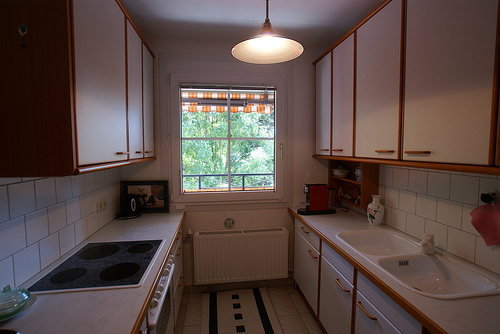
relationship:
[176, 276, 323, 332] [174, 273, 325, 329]
tiles on floor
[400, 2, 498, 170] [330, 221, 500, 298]
cabinet above sink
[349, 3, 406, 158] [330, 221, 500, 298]
cabinet above sink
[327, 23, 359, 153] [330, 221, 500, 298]
cabinet above sink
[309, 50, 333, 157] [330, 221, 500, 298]
cabinet above sink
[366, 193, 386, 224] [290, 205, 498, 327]
dish on countertop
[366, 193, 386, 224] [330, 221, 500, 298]
vase next to sink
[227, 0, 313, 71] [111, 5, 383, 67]
light hanging from ceiling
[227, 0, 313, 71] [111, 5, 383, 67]
light on ceiling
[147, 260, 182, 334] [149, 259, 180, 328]
stove with handle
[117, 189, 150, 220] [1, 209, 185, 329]
kettle on counter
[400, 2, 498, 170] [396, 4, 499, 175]
cabinet with frame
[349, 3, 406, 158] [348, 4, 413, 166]
cabinet with frame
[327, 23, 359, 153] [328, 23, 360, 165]
cabinet with frame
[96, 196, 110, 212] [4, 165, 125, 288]
outlet on wall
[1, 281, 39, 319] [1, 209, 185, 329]
dish on counter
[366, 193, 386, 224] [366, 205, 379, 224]
vase with design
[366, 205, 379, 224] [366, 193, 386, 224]
design on vase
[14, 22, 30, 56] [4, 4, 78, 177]
picture on end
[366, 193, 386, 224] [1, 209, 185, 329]
dish on counter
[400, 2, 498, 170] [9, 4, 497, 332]
cabinet in kitchen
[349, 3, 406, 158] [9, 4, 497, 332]
cabinet in kitchen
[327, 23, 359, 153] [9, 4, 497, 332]
cabinet in kitchen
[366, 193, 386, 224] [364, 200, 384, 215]
vase with flower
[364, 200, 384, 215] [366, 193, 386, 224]
flower on vase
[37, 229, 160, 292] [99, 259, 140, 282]
stovetop with element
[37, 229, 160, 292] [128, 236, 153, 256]
stovetop with element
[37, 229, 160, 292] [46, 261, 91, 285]
stovetop with element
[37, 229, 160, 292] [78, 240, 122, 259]
stovetop with element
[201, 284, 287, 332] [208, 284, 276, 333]
runner with stripes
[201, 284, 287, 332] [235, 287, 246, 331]
runner with dashes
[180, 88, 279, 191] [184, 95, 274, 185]
window with view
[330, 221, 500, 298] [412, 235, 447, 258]
sink with faucet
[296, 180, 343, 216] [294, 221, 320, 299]
appliance on cabinet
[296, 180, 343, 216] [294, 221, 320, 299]
appliance sitting on cabinet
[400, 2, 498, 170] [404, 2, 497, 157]
cabinet with door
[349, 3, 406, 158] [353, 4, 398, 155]
cabinet with door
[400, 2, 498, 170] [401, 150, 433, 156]
cabinet with cabinet handle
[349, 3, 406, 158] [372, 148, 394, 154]
cabinet with cabinet handle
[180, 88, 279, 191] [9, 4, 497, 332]
window back of kitchen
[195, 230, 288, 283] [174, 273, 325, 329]
unit toward floor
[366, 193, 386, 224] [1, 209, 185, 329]
vase on counter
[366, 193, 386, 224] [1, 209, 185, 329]
vase top of counter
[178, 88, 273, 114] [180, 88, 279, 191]
over hang on window